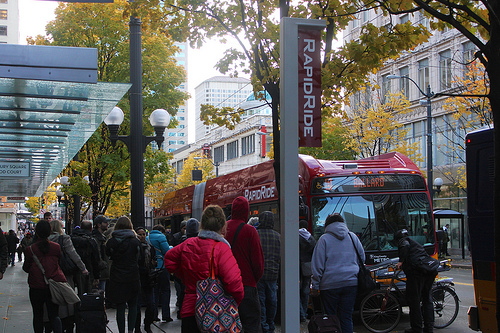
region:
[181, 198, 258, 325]
A woman in a red jacket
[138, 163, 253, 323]
A woman in a red jacket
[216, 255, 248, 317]
A woman in a red jacket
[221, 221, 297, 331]
A woman in a red jacket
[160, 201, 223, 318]
A woman in a red jacket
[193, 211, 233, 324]
A woman in a red jacket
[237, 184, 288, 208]
rapid ride on bus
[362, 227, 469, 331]
person with bike in front of bus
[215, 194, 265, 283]
person wearing red hoodie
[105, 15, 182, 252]
light pole with dual lamps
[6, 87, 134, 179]
clear plexi glass roof over bus stop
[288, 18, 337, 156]
rapid ride flag on pole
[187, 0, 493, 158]
buildings in the background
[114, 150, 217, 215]
yellow leaves on trees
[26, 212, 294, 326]
lots of people getting on bus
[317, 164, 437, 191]
orange lights on bus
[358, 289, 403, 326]
front wheel on bicycle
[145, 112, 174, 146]
a street light on pole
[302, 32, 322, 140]
a bus stop sign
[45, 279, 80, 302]
bottom part of woman's purse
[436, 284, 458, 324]
back wheel on bicycle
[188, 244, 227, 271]
pink jacket on woman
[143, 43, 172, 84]
leaves on the tree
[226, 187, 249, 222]
red hood on coat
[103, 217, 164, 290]
passengers for the bus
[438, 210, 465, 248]
a bus stop stand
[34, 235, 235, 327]
The crowd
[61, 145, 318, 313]
The crowd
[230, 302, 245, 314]
The crowd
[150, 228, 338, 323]
The crowd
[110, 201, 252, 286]
The crowd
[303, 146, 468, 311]
the red colored bus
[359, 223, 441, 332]
a man with bicycle in front of the bus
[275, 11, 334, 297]
the sign board with red color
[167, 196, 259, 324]
a women in pink color jacket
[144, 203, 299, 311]
group of people waiting for bus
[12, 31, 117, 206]
the shelter in the bus stand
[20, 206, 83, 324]
a girl with red shirt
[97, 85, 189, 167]
the white color street lights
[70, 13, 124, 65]
the green color trees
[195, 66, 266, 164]
the buildings on the roadside